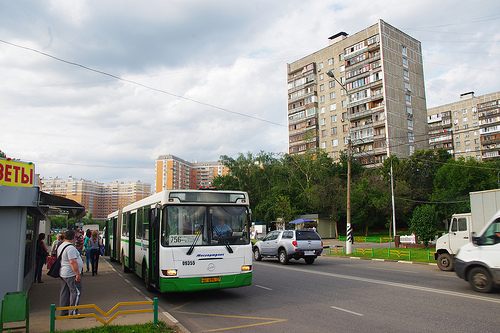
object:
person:
[88, 229, 103, 278]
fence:
[386, 248, 411, 261]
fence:
[48, 295, 164, 331]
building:
[284, 18, 428, 169]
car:
[450, 209, 499, 295]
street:
[97, 252, 500, 332]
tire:
[467, 266, 494, 294]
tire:
[253, 247, 262, 261]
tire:
[435, 251, 455, 272]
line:
[329, 304, 366, 316]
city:
[0, 20, 499, 332]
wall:
[380, 18, 426, 161]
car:
[251, 227, 327, 265]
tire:
[278, 249, 291, 265]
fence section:
[328, 246, 345, 256]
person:
[57, 228, 87, 319]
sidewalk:
[0, 254, 194, 332]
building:
[426, 89, 500, 165]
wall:
[0, 205, 27, 297]